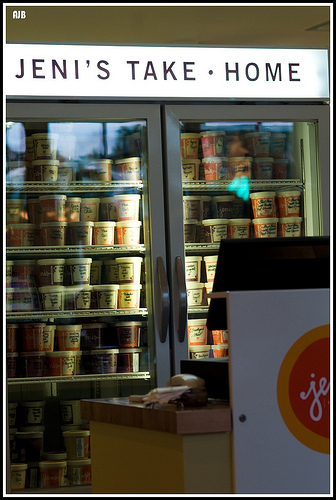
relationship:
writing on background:
[297, 368, 333, 421] [276, 325, 330, 455]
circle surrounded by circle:
[290, 335, 327, 438] [271, 326, 332, 470]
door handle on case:
[156, 256, 169, 343] [6, 103, 331, 498]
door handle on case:
[175, 256, 187, 343] [6, 103, 331, 498]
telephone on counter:
[161, 366, 204, 405] [76, 390, 229, 430]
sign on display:
[4, 43, 335, 99] [6, 42, 330, 102]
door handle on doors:
[156, 256, 169, 343] [2, 100, 322, 232]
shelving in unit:
[5, 371, 151, 387] [6, 41, 324, 497]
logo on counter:
[257, 336, 329, 403] [210, 288, 327, 492]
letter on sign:
[15, 59, 302, 84] [4, 43, 335, 99]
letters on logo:
[299, 373, 328, 421] [277, 324, 330, 455]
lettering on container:
[78, 264, 88, 278] [69, 258, 83, 283]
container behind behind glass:
[7, 130, 302, 489] [23, 130, 118, 182]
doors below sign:
[2, 104, 171, 494] [6, 44, 329, 99]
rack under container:
[6, 180, 145, 191] [30, 130, 56, 158]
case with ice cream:
[6, 103, 331, 498] [113, 193, 142, 223]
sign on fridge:
[6, 44, 329, 99] [4, 101, 330, 496]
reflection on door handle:
[161, 291, 187, 305] [156, 256, 169, 343]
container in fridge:
[117, 217, 143, 242] [0, 101, 201, 353]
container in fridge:
[7, 130, 302, 489] [0, 101, 201, 353]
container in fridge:
[65, 255, 91, 280] [0, 101, 201, 353]